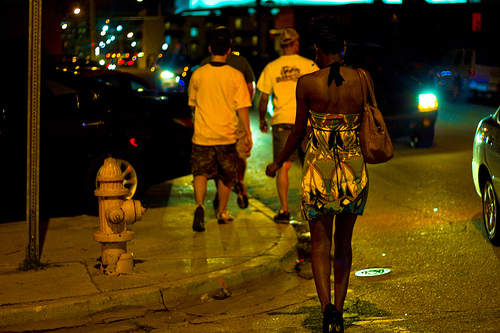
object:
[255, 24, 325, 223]
man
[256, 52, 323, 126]
shirt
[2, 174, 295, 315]
sidewalk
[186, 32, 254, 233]
man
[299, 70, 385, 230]
elephant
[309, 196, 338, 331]
leg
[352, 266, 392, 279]
drain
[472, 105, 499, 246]
car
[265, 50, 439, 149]
car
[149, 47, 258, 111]
car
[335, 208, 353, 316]
leg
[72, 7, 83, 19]
light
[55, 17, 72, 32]
light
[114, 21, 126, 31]
light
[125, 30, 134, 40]
light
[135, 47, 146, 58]
light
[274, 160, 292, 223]
leg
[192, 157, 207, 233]
leg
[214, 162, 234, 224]
leg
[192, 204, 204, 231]
sandal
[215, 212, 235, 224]
sandal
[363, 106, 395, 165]
purse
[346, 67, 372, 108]
shoulder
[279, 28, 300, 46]
cap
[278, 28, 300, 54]
head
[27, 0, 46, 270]
pole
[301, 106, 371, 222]
dress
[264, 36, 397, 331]
person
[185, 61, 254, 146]
shirt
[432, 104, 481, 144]
ground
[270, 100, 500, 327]
street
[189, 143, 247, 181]
shorts